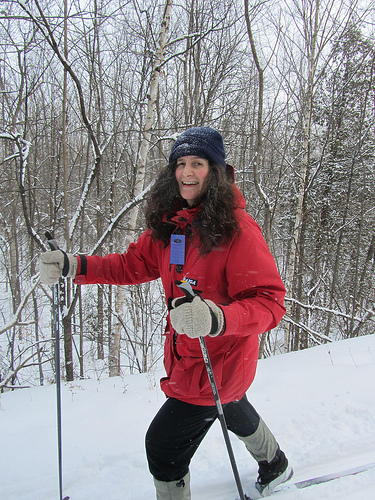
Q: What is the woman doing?
A: Skiing.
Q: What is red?
A: Woman's jacket.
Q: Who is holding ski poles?
A: The woman.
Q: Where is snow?
A: On the trees.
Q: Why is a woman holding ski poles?
A: To ski.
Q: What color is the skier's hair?
A: Brown.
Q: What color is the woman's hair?
A: Dark brown.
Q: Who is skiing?
A: The woman.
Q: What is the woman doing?
A: Skiing.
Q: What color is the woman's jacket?
A: Red.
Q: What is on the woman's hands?
A: Gloves.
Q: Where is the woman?
A: On a ski slope.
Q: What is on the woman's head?
A: A beanie.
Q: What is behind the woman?
A: Trees.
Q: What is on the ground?
A: Snow.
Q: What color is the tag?
A: Blue.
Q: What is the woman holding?
A: Ski poles.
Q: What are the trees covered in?
A: Snow.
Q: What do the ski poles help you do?
A: Move.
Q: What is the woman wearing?
A: Jacket.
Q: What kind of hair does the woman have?
A: Curly.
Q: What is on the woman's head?
A: Hat.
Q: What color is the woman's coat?
A: Red.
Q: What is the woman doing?
A: Cross country skiing.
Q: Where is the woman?
A: Outdoors on a path.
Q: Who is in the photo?
A: A woman.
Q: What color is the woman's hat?
A: Blue.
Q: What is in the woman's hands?
A: Poles.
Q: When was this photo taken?
A: Daytime.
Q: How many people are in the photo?
A: One.